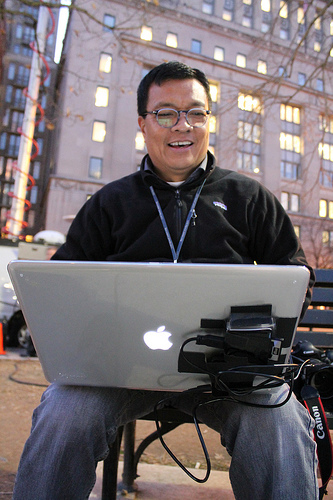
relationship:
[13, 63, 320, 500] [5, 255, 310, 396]
man has laptop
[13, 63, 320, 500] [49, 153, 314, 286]
man wearing pullover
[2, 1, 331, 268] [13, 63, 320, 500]
building behind man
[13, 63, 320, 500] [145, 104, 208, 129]
man wearing glasses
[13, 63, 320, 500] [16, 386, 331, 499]
man wearing jeans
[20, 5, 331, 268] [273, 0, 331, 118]
tree has branches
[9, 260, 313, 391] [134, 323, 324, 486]
computer has wires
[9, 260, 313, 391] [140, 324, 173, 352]
laptop has logo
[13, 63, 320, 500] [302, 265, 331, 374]
man sitting on bench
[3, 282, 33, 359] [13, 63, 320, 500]
car behind man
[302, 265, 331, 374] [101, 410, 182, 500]
bench has legs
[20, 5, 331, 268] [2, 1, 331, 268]
tree in background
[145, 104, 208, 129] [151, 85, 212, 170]
glasses are on h face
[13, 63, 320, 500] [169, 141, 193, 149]
man has teeth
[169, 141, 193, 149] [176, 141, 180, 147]
teeth have a gap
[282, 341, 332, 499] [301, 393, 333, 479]
camera has a strap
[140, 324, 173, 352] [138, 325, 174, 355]
logo of apple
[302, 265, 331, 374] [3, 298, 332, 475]
bench in park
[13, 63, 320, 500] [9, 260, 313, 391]
man using laptop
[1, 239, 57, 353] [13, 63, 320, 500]
tv van behind man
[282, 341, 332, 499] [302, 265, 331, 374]
camera sitting on bench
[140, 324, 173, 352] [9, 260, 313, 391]
logo on top of laptop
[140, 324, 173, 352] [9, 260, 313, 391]
logo on laptop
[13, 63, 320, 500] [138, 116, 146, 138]
man has an ear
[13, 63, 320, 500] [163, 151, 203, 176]
man has a chin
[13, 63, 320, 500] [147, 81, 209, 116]
man has forehead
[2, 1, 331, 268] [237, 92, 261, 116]
building has a window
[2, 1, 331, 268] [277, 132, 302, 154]
building has a window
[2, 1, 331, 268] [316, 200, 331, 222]
building has a window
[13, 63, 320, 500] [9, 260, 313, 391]
man holding laptop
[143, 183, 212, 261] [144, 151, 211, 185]
lanyard around neck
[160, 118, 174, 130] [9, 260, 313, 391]
reflection of laptop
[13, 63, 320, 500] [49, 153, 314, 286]
man wearing jacket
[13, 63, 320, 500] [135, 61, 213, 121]
man has hair